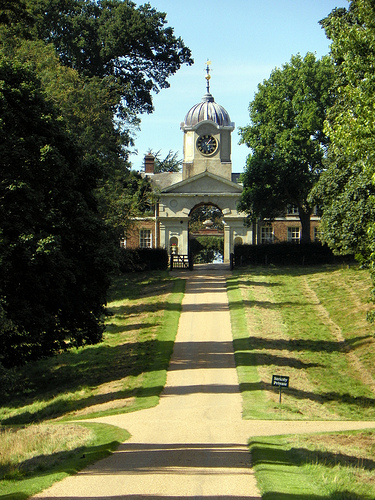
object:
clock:
[196, 133, 219, 157]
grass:
[286, 281, 351, 346]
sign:
[271, 374, 290, 388]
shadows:
[0, 334, 374, 380]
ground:
[2, 268, 375, 500]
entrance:
[188, 202, 224, 267]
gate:
[172, 253, 191, 269]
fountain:
[202, 217, 214, 231]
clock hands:
[206, 136, 216, 146]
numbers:
[198, 132, 217, 153]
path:
[104, 283, 262, 497]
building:
[117, 58, 324, 268]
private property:
[272, 374, 289, 387]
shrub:
[132, 247, 169, 272]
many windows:
[119, 221, 319, 250]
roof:
[179, 96, 234, 127]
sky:
[152, 1, 290, 127]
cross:
[204, 56, 212, 74]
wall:
[126, 218, 138, 249]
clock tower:
[180, 93, 234, 176]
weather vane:
[205, 64, 212, 74]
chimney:
[143, 153, 155, 174]